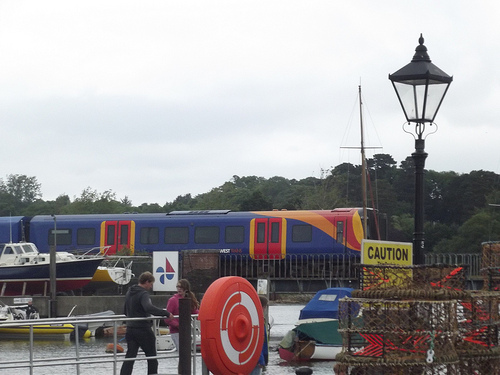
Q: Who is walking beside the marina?
A: A couple.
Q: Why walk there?
A: A pleasant place to stroll.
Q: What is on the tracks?
A: A railroad car.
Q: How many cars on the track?
A: At least 2.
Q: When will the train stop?
A: At the destination.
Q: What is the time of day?
A: Late afternoon.